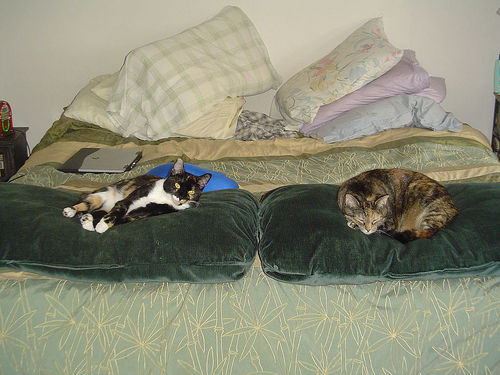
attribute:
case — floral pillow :
[278, 14, 399, 108]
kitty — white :
[63, 156, 211, 244]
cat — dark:
[61, 155, 212, 234]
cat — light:
[334, 165, 462, 244]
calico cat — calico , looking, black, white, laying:
[64, 158, 210, 234]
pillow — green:
[259, 174, 497, 283]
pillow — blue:
[142, 164, 238, 192]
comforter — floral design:
[2, 130, 499, 374]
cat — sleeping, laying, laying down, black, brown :
[336, 168, 457, 240]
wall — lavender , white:
[1, 3, 499, 146]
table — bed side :
[0, 124, 28, 181]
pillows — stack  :
[275, 15, 463, 141]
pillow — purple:
[298, 48, 430, 134]